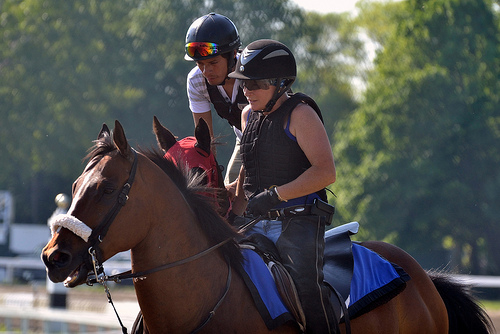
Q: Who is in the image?
A: Jockeys.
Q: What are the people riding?
A: Horses.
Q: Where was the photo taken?
A: A horse track.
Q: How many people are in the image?
A: Two.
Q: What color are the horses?
A: Brown.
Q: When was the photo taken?
A: Daytime.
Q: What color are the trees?
A: Green.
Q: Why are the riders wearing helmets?
A: Safety.